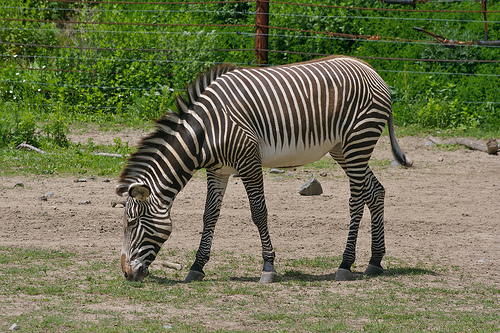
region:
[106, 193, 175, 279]
the zebra is eating the grass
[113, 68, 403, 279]
a zebra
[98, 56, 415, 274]
the zebra is black and white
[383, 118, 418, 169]
the zebras tail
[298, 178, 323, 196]
a rock on the ground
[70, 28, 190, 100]
the bush is green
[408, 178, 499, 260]
the dirt on the ground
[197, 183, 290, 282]
the zebras leg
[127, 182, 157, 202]
the ear on the zebra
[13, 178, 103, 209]
rocks on the ground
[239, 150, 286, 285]
Left front foreleg of a zebra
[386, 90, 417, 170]
Tail of zebra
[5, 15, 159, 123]
Part of fence enclosure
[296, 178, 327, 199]
gray rock on the ground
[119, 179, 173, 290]
head of an eating zebra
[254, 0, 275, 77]
part of a metal fence post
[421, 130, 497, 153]
Dead tree branch on ground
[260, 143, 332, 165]
white stomach of a zebra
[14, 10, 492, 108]
green brush behind a metal fence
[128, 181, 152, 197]
the left ear of a zebra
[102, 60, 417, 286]
a zebra eating grass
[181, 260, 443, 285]
shadow of zebra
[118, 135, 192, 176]
a hair on zebra's neck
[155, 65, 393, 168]
brown and white colour stripes zebra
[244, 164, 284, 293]
front leg of the zebra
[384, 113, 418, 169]
a tail of the zebra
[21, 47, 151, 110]
lot of green plants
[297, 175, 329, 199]
a stone in the dirt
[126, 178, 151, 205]
ear of zebra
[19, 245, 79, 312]
a place of grass and dirt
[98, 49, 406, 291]
black and white striped zebra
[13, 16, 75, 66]
green leaves on the plants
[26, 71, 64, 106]
green leaves on the plants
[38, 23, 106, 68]
green leaves on the plants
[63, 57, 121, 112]
green leaves on the plants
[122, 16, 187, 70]
green leaves on the plants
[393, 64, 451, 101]
green leaves on the plants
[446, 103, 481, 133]
green leaves on the plants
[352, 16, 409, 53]
green leaves on the plants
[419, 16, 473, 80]
green leaves on the plants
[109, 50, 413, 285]
White and black zebra eating grass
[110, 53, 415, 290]
Zebra swinging long tail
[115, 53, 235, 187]
Black and white mane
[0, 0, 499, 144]
Fence behind black and white zebra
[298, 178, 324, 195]
Gray rock on dirt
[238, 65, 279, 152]
Long brown line on zebra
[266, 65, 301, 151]
Long brown line on zebra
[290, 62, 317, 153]
Long brown line on zebra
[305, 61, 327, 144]
Long brown line on zebra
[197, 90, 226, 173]
Long brown line on zebra